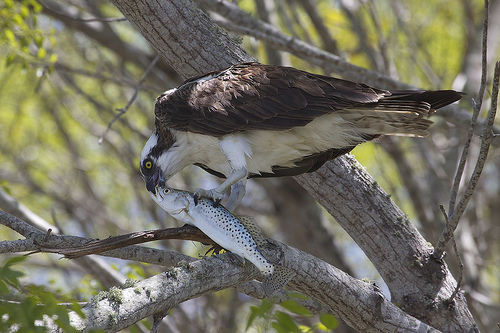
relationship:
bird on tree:
[138, 62, 466, 209] [5, 0, 494, 331]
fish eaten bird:
[129, 161, 317, 298] [153, 70, 375, 165]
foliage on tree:
[0, 82, 108, 329] [25, 23, 497, 331]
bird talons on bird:
[193, 188, 225, 208] [137, 58, 462, 212]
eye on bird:
[143, 157, 153, 169] [137, 58, 462, 212]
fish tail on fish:
[261, 264, 296, 298] [145, 180, 296, 300]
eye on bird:
[143, 158, 153, 168] [97, 67, 497, 189]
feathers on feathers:
[191, 68, 411, 129] [187, 62, 392, 131]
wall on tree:
[252, 192, 313, 212] [113, 5, 260, 79]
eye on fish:
[161, 187, 171, 196] [151, 184, 275, 279]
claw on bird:
[193, 192, 203, 207] [137, 58, 462, 212]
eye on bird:
[143, 158, 153, 168] [92, 54, 463, 223]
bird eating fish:
[137, 58, 462, 212] [140, 173, 281, 280]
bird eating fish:
[137, 58, 462, 212] [151, 184, 275, 279]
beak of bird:
[142, 163, 162, 195] [137, 74, 462, 204]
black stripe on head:
[138, 119, 181, 167] [144, 137, 191, 195]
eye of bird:
[143, 158, 153, 168] [137, 58, 462, 212]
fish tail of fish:
[260, 263, 297, 298] [145, 180, 296, 300]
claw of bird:
[194, 194, 198, 207] [137, 58, 462, 212]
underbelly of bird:
[196, 121, 329, 175] [130, 57, 458, 197]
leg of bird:
[186, 168, 246, 203] [137, 58, 462, 212]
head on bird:
[132, 122, 182, 192] [130, 57, 458, 197]